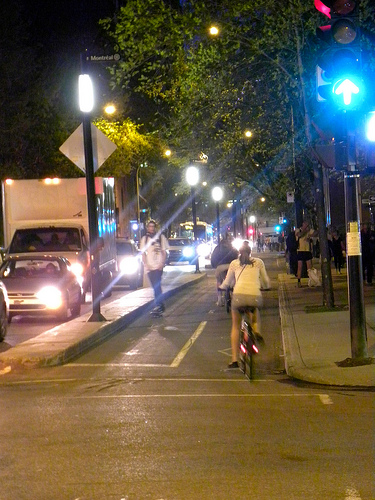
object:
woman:
[218, 241, 269, 369]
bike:
[218, 287, 272, 380]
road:
[0, 357, 375, 500]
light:
[76, 73, 95, 113]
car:
[0, 255, 81, 322]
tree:
[100, 0, 337, 312]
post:
[76, 53, 105, 324]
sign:
[59, 120, 121, 176]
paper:
[345, 220, 363, 255]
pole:
[343, 165, 371, 360]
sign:
[315, 0, 375, 368]